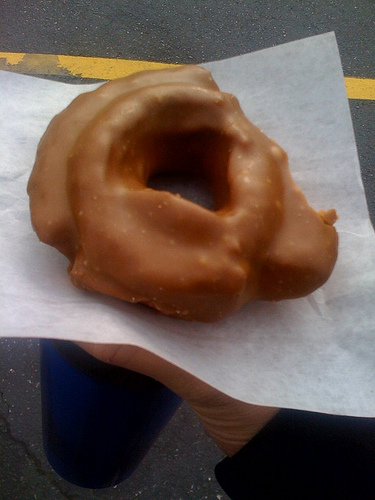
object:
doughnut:
[28, 63, 339, 322]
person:
[36, 243, 375, 496]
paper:
[0, 29, 373, 412]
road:
[4, 0, 374, 134]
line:
[1, 49, 373, 109]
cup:
[36, 322, 186, 494]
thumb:
[56, 332, 226, 400]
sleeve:
[212, 392, 374, 497]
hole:
[143, 123, 232, 219]